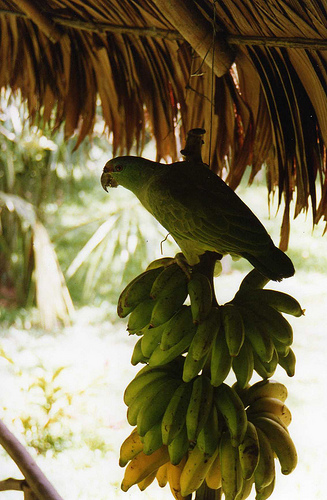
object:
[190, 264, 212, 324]
banana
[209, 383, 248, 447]
banana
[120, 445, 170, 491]
banana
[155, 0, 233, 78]
bamboo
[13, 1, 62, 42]
bamboo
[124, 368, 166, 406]
bananas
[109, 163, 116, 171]
eye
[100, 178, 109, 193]
beak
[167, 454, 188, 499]
banana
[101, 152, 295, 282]
bird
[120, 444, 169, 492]
bananas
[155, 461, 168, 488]
bananas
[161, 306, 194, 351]
banana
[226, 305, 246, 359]
banana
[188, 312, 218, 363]
banana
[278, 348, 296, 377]
banana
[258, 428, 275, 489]
banana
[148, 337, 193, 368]
banana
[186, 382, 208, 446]
banana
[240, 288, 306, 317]
banana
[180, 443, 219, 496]
banana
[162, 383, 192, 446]
banana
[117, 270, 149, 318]
banana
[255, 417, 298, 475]
banana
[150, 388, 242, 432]
bunch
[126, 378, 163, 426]
bananas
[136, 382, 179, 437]
bananas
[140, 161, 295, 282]
feathers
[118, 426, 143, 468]
bananas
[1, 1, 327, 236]
hut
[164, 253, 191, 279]
foot